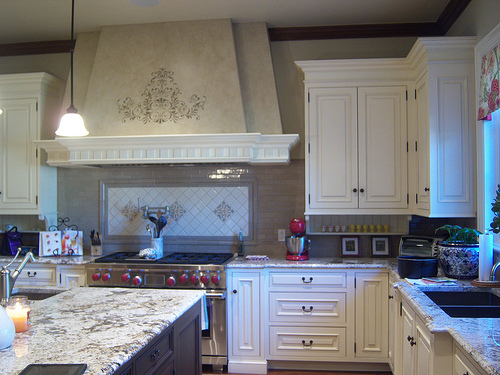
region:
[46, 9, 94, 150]
light in a kitchen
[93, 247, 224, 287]
stove in a kitchen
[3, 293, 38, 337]
candle on a countertop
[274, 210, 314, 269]
coffee pot on a counter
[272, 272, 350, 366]
white cabinets in a kitchen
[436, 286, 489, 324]
sink in a kitchen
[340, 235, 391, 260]
frames on a countertop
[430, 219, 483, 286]
potted plant by window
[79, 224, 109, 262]
knife block on a counter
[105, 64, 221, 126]
decoration on an oven hood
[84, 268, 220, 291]
red knobs on stove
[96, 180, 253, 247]
back wall is tiled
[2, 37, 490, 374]
the cabinets are white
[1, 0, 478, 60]
brown frame on wall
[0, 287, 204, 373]
counter made from marble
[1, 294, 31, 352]
candles on the counter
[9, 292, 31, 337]
the candle is lit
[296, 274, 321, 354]
black handles on drawers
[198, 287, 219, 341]
towel hanging on stove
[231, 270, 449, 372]
White cupboards under the counter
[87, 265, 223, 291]
Knobs and dials on the front of the stove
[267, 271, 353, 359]
Closed white drawers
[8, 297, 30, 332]
A lit candle on table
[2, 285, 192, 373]
A white and gray marble countertop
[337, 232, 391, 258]
Two pictures above the counter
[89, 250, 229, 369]
A silver stove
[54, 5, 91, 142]
A light hanging from the ceiling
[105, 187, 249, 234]
White tiles above the stove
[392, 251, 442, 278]
A black pot on the counter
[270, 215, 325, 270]
mixer with stainless steal bowle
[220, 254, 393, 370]
white cabinets with metal puller handles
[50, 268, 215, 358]
granit counter top with black running between it.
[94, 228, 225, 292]
stove with red knobs and stainless steal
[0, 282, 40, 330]
candle that is lit with a flame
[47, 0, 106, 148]
long light fixture with light on.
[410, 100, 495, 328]
natural light coming in through a window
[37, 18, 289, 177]
large vent with fancy design on it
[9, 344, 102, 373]
phone or tablet on counter top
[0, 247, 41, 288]
stainless steal water ficture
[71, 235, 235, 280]
this is a stove top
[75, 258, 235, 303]
the stove has red knobs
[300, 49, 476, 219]
these cupboards are white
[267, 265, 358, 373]
the drawers are white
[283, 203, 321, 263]
this is a mixer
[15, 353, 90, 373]
this is a tablet computer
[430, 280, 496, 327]
this is the sink basin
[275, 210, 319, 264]
the electric mixer is red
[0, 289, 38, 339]
this is a candle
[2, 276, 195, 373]
this is a marble countertop